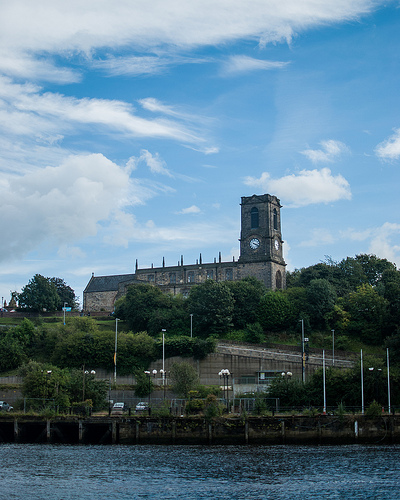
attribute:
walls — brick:
[238, 260, 272, 287]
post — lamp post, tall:
[159, 327, 168, 409]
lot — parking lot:
[3, 394, 391, 413]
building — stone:
[82, 193, 290, 319]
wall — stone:
[2, 346, 393, 404]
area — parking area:
[0, 402, 400, 416]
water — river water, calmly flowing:
[2, 442, 399, 498]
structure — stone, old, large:
[84, 194, 292, 321]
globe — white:
[226, 371, 231, 374]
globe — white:
[223, 367, 229, 373]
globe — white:
[221, 369, 226, 374]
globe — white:
[218, 371, 223, 375]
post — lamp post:
[220, 373, 231, 415]